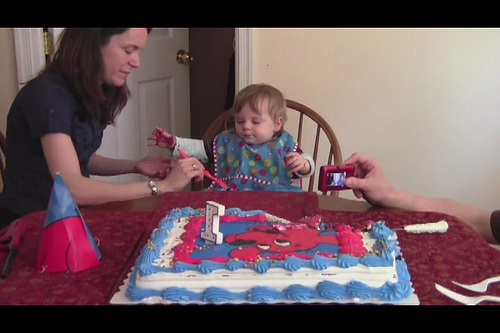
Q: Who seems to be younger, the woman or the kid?
A: The kid is younger than the woman.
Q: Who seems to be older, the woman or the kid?
A: The woman is older than the kid.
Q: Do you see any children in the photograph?
A: Yes, there is a child.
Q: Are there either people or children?
A: Yes, there is a child.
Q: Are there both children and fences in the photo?
A: No, there is a child but no fences.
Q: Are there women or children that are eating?
A: Yes, the child is eating.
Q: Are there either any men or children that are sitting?
A: Yes, the child is sitting.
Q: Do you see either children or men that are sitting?
A: Yes, the child is sitting.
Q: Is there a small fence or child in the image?
A: Yes, there is a small child.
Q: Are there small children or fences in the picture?
A: Yes, there is a small child.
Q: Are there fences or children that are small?
A: Yes, the child is small.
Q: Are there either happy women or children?
A: Yes, there is a happy child.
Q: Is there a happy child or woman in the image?
A: Yes, there is a happy child.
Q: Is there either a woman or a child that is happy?
A: Yes, the child is happy.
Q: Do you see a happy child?
A: Yes, there is a happy child.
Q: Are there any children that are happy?
A: Yes, there is a child that is happy.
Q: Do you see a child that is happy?
A: Yes, there is a child that is happy.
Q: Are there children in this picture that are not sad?
A: Yes, there is a happy child.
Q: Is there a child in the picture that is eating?
A: Yes, there is a child that is eating.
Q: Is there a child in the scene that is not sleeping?
A: Yes, there is a child that is eating.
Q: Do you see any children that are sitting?
A: Yes, there is a child that is sitting.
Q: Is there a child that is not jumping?
A: Yes, there is a child that is sitting.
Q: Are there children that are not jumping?
A: Yes, there is a child that is sitting.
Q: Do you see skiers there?
A: No, there are no skiers.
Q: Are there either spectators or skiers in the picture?
A: No, there are no skiers or spectators.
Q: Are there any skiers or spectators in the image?
A: No, there are no skiers or spectators.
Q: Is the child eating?
A: Yes, the child is eating.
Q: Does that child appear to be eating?
A: Yes, the child is eating.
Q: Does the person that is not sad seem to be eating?
A: Yes, the child is eating.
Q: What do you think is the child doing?
A: The child is eating.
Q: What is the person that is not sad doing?
A: The child is eating.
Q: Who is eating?
A: The kid is eating.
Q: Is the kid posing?
A: No, the kid is eating.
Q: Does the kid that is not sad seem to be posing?
A: No, the child is eating.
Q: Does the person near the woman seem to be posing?
A: No, the child is eating.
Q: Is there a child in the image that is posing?
A: No, there is a child but he is eating.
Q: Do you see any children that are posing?
A: No, there is a child but he is eating.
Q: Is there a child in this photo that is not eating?
A: No, there is a child but he is eating.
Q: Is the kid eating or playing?
A: The kid is eating.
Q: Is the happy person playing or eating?
A: The kid is eating.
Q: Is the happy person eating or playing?
A: The kid is eating.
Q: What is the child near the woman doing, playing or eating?
A: The kid is eating.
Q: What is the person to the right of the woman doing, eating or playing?
A: The kid is eating.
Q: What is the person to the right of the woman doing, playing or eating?
A: The kid is eating.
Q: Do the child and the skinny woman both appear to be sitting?
A: Yes, both the child and the woman are sitting.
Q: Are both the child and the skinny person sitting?
A: Yes, both the child and the woman are sitting.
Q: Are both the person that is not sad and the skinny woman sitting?
A: Yes, both the child and the woman are sitting.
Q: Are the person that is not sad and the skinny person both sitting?
A: Yes, both the child and the woman are sitting.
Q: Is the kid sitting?
A: Yes, the kid is sitting.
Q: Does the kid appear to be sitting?
A: Yes, the kid is sitting.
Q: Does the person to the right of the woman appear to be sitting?
A: Yes, the kid is sitting.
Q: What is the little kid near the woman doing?
A: The child is sitting.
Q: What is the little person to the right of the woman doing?
A: The child is sitting.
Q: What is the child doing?
A: The child is sitting.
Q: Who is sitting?
A: The kid is sitting.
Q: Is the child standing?
A: No, the child is sitting.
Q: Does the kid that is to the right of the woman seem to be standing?
A: No, the kid is sitting.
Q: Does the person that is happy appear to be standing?
A: No, the kid is sitting.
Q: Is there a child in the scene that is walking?
A: No, there is a child but he is sitting.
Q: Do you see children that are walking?
A: No, there is a child but he is sitting.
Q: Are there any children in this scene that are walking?
A: No, there is a child but he is sitting.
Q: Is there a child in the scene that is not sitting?
A: No, there is a child but he is sitting.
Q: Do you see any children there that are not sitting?
A: No, there is a child but he is sitting.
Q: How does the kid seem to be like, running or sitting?
A: The kid is sitting.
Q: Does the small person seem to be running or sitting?
A: The kid is sitting.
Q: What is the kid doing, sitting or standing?
A: The kid is sitting.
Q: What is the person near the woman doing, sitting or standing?
A: The kid is sitting.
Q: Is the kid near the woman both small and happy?
A: Yes, the child is small and happy.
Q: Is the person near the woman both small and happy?
A: Yes, the child is small and happy.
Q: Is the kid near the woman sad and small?
A: No, the child is small but happy.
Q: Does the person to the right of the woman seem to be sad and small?
A: No, the child is small but happy.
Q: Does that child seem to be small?
A: Yes, the child is small.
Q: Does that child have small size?
A: Yes, the child is small.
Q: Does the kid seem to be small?
A: Yes, the kid is small.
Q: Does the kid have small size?
A: Yes, the kid is small.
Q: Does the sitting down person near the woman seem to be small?
A: Yes, the kid is small.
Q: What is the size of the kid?
A: The kid is small.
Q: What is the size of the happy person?
A: The kid is small.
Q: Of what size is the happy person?
A: The kid is small.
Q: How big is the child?
A: The child is small.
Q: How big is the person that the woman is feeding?
A: The child is small.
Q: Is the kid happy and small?
A: Yes, the kid is happy and small.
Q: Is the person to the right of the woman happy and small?
A: Yes, the kid is happy and small.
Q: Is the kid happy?
A: Yes, the kid is happy.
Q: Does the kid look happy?
A: Yes, the kid is happy.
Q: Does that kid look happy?
A: Yes, the kid is happy.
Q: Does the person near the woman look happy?
A: Yes, the kid is happy.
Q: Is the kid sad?
A: No, the kid is happy.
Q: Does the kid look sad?
A: No, the kid is happy.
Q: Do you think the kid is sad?
A: No, the kid is happy.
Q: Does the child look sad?
A: No, the child is happy.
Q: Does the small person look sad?
A: No, the child is happy.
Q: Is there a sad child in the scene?
A: No, there is a child but he is happy.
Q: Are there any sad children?
A: No, there is a child but he is happy.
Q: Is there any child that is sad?
A: No, there is a child but he is happy.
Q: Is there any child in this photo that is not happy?
A: No, there is a child but he is happy.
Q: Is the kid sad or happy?
A: The kid is happy.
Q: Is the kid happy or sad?
A: The kid is happy.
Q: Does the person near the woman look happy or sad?
A: The kid is happy.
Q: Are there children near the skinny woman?
A: Yes, there is a child near the woman.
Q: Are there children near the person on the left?
A: Yes, there is a child near the woman.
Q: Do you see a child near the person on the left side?
A: Yes, there is a child near the woman.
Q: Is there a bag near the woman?
A: No, there is a child near the woman.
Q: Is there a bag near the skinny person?
A: No, there is a child near the woman.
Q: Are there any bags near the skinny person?
A: No, there is a child near the woman.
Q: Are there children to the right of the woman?
A: Yes, there is a child to the right of the woman.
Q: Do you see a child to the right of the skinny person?
A: Yes, there is a child to the right of the woman.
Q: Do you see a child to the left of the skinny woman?
A: No, the child is to the right of the woman.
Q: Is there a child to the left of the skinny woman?
A: No, the child is to the right of the woman.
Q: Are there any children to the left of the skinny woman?
A: No, the child is to the right of the woman.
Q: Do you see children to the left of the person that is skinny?
A: No, the child is to the right of the woman.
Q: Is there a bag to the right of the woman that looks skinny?
A: No, there is a child to the right of the woman.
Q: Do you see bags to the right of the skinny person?
A: No, there is a child to the right of the woman.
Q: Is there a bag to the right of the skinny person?
A: No, there is a child to the right of the woman.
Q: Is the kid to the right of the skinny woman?
A: Yes, the kid is to the right of the woman.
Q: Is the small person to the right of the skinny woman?
A: Yes, the kid is to the right of the woman.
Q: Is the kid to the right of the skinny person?
A: Yes, the kid is to the right of the woman.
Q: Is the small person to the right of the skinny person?
A: Yes, the kid is to the right of the woman.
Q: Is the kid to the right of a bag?
A: No, the kid is to the right of the woman.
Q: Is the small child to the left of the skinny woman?
A: No, the kid is to the right of the woman.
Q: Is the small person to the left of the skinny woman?
A: No, the kid is to the right of the woman.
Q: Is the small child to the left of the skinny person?
A: No, the kid is to the right of the woman.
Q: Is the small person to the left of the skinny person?
A: No, the kid is to the right of the woman.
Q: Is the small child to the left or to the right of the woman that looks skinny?
A: The kid is to the right of the woman.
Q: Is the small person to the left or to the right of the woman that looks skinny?
A: The kid is to the right of the woman.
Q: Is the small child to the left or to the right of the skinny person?
A: The kid is to the right of the woman.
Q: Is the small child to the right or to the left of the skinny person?
A: The kid is to the right of the woman.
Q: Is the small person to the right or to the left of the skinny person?
A: The kid is to the right of the woman.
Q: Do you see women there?
A: Yes, there is a woman.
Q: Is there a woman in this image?
A: Yes, there is a woman.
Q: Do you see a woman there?
A: Yes, there is a woman.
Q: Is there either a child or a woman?
A: Yes, there is a woman.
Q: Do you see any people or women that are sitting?
A: Yes, the woman is sitting.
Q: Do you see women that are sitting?
A: Yes, there is a woman that is sitting.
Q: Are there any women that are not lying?
A: Yes, there is a woman that is sitting.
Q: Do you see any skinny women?
A: Yes, there is a skinny woman.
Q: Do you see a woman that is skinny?
A: Yes, there is a woman that is skinny.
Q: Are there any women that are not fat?
A: Yes, there is a skinny woman.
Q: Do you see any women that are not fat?
A: Yes, there is a skinny woman.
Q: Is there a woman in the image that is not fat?
A: Yes, there is a skinny woman.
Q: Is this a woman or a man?
A: This is a woman.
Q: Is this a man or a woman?
A: This is a woman.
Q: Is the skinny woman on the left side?
A: Yes, the woman is on the left of the image.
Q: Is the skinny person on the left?
A: Yes, the woman is on the left of the image.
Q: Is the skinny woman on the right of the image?
A: No, the woman is on the left of the image.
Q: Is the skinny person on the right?
A: No, the woman is on the left of the image.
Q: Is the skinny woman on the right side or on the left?
A: The woman is on the left of the image.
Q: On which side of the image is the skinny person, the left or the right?
A: The woman is on the left of the image.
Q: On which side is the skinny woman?
A: The woman is on the left of the image.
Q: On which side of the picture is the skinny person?
A: The woman is on the left of the image.